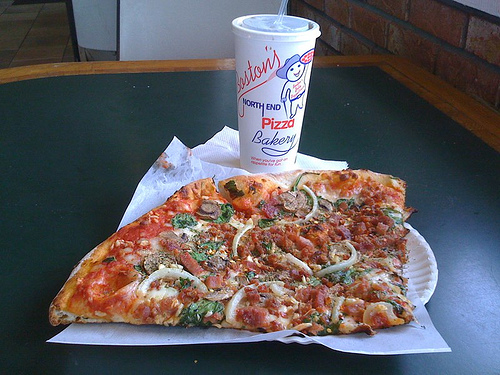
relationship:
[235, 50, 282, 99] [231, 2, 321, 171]
boston on cup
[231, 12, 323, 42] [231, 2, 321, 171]
lid on cup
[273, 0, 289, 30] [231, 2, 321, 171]
straw in cup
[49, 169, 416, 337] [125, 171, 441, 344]
slices of  pizza on plate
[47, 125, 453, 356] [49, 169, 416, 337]
paper under slices of  pizza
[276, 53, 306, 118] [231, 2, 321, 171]
figure on cup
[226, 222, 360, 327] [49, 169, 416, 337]
onions and sausage on slices of  pizza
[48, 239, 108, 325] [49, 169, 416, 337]
crust of slices of  pizza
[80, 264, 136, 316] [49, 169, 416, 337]
tomato sauce on slices of  pizza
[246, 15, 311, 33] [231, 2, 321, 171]
soda in cup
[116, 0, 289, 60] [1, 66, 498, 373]
object behind table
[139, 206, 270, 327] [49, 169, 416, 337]
toppings on slices of  pizza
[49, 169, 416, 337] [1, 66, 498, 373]
slices of  pizza on table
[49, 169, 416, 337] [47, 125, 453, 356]
slices of  pizza on top of paper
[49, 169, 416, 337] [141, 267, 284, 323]
slices of  pizza has onions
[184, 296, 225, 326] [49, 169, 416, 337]
basil on slices of  pizza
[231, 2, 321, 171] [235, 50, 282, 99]
cup says boston